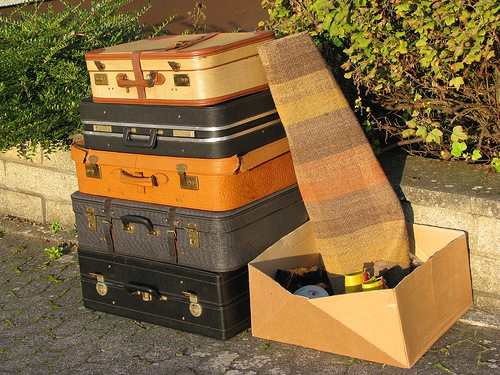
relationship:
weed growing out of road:
[46, 244, 64, 259] [2, 222, 499, 372]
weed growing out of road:
[52, 222, 64, 235] [2, 222, 499, 372]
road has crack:
[2, 222, 499, 372] [16, 254, 33, 274]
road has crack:
[2, 222, 499, 372] [47, 314, 69, 334]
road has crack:
[2, 222, 499, 372] [49, 286, 72, 305]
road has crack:
[2, 222, 499, 372] [95, 322, 116, 340]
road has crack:
[2, 222, 499, 372] [4, 337, 24, 354]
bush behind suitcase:
[2, 1, 205, 152] [71, 141, 297, 213]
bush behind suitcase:
[259, 0, 500, 166] [71, 141, 297, 213]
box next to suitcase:
[248, 216, 475, 370] [76, 244, 251, 339]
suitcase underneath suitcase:
[76, 244, 251, 339] [68, 182, 310, 272]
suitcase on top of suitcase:
[68, 182, 310, 272] [76, 244, 251, 339]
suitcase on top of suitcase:
[80, 89, 287, 158] [71, 141, 297, 213]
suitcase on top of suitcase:
[84, 29, 278, 108] [80, 89, 287, 158]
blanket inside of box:
[255, 29, 412, 293] [248, 216, 475, 370]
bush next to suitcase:
[2, 1, 205, 152] [84, 29, 278, 108]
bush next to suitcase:
[259, 0, 500, 166] [84, 29, 278, 108]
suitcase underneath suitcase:
[68, 182, 310, 272] [71, 141, 297, 213]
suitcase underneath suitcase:
[71, 141, 297, 213] [80, 89, 287, 158]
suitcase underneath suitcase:
[80, 89, 287, 158] [84, 29, 278, 108]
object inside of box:
[343, 266, 395, 296] [248, 216, 475, 370]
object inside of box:
[294, 283, 329, 300] [248, 216, 475, 370]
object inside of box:
[274, 265, 324, 294] [248, 216, 475, 370]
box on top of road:
[248, 216, 475, 370] [2, 222, 499, 372]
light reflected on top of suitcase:
[188, 55, 213, 105] [84, 29, 278, 108]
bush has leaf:
[2, 1, 205, 152] [45, 149, 56, 153]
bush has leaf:
[2, 1, 205, 152] [16, 152, 26, 160]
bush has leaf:
[2, 1, 205, 152] [61, 146, 67, 151]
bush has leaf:
[2, 1, 205, 152] [69, 29, 79, 39]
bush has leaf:
[2, 1, 205, 152] [32, 35, 38, 45]